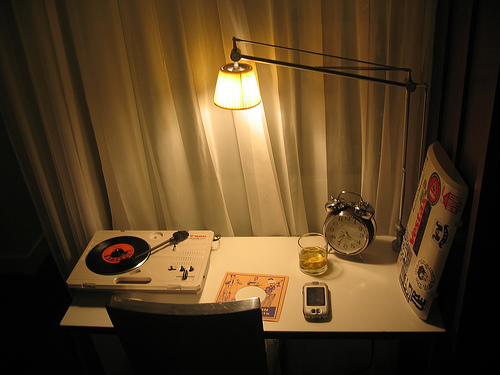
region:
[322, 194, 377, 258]
a metal alarm clock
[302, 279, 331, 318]
a grey cellular phone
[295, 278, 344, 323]
a phone on a desktop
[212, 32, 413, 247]
a desk lamp turned on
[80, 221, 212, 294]
a record player with a record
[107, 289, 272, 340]
the back of a chair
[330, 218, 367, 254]
the face of a clock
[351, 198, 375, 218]
a bell on an alarm clock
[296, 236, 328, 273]
a drink in a clear glass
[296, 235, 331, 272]
a clear drinking glass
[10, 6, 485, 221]
lamp in front of white draperies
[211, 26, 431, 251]
metal poles supporting extending lamp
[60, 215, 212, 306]
black vinyl record with red label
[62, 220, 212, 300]
record on flat white turntable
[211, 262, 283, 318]
paper cover for record with hole in center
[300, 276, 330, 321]
silver cellphone with dark panel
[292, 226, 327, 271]
short transparent glass with yellow liquid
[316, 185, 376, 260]
upright silver alarm clock on legs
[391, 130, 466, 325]
oval container with words and pictures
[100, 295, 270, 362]
back of wooden chair by table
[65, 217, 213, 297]
Turntable sitting on desk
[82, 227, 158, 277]
Black and orange record on the turntable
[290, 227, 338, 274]
Glass cup with yellow liquid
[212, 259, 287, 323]
Purple and orange empty record container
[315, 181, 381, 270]
Old style alarm clock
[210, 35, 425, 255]
Table lamp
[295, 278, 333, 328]
Small digital device on table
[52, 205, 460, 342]
White table next to wall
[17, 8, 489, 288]
White curtains behind desk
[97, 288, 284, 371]
Black chair at desk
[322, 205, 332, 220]
;part of a clck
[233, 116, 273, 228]
part of a lined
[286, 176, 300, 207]
part of a curtain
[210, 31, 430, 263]
a lampshade on the table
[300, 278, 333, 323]
a cellphone on the table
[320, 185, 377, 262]
a clock on the table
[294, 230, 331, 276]
a glass on the table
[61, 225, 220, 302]
a player on the table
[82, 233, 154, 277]
a black disc on the player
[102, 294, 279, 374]
a chair on the table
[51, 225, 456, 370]
a table and a chair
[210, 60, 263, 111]
a lampshade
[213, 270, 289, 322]
a disc shield on the table